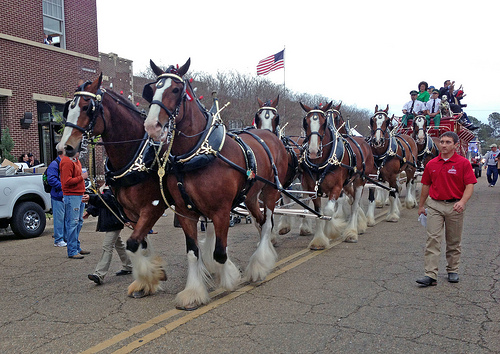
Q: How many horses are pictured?
A: 8.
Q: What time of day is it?
A: Day time.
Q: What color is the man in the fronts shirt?
A: Red.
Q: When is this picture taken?
A: During parade.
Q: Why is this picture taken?
A: Photography.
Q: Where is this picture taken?
A: From of parade.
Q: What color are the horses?
A: Brown and white.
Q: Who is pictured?
A: Community.